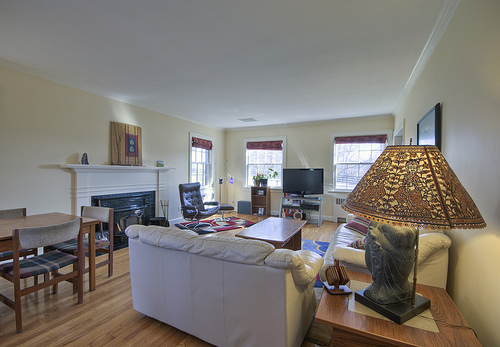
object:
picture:
[106, 119, 144, 167]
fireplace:
[88, 190, 155, 252]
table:
[0, 211, 99, 293]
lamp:
[339, 144, 489, 326]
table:
[313, 269, 484, 347]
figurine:
[361, 219, 418, 305]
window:
[245, 162, 286, 189]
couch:
[318, 211, 453, 290]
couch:
[124, 223, 327, 346]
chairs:
[42, 204, 116, 295]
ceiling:
[0, 0, 456, 134]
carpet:
[172, 215, 257, 236]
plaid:
[0, 245, 78, 280]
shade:
[339, 145, 488, 232]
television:
[281, 167, 324, 198]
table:
[233, 215, 307, 252]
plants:
[252, 167, 279, 181]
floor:
[0, 210, 346, 346]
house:
[1, 1, 500, 346]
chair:
[178, 182, 221, 232]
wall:
[392, 0, 500, 346]